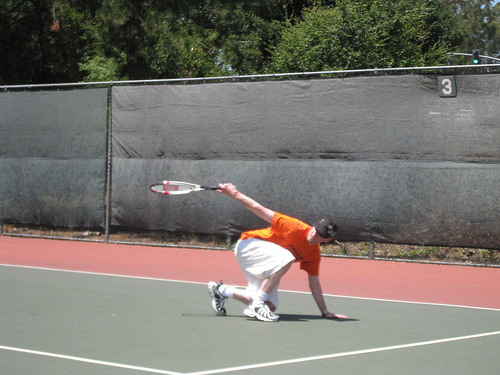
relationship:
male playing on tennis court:
[206, 182, 347, 323] [0, 266, 497, 372]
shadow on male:
[276, 302, 344, 327] [206, 182, 347, 323]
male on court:
[206, 182, 347, 323] [0, 230, 498, 374]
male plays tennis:
[206, 182, 347, 323] [150, 181, 231, 195]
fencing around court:
[1, 69, 493, 249] [0, 230, 498, 374]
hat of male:
[299, 202, 369, 247] [206, 182, 347, 323]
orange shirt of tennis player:
[240, 212, 321, 278] [209, 182, 349, 320]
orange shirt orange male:
[260, 212, 320, 258] [209, 182, 349, 321]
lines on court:
[17, 310, 471, 368] [0, 230, 498, 374]